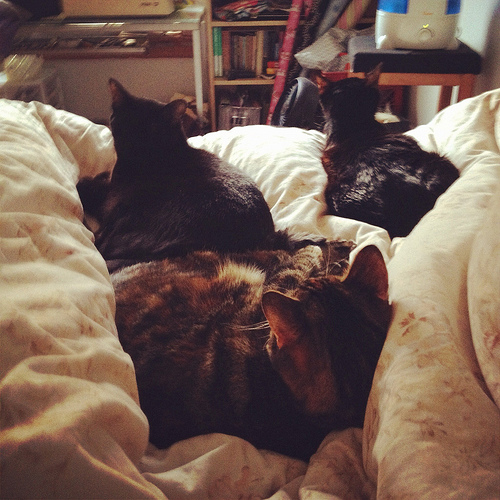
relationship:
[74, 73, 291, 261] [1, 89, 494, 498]
cat are on bed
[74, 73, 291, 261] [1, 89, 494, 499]
cat are on room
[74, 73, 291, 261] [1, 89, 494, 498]
cat are in bed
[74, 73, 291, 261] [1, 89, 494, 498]
cat are lying on a bed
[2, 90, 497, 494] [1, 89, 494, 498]
blanket on bed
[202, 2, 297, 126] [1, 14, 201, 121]
bookcase against wall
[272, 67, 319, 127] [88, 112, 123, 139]
fan on floor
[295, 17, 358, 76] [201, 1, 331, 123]
paper rolls against bookcase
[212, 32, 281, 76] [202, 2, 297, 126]
books on bookcase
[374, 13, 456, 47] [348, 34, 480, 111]
humidifier on table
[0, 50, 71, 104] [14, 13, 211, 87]
storage under desk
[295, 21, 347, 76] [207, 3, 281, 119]
paper rolls on bookcase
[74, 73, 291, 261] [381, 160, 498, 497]
cat on comforter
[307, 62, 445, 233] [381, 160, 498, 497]
cat on comforter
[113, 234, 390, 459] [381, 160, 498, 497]
cat on comforter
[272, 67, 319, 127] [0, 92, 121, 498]
fan beside bed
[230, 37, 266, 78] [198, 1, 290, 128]
books on bookshelf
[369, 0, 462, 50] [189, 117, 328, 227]
humidifier beside bed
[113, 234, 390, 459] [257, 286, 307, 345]
cat has ear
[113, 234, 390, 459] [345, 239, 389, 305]
cat has ear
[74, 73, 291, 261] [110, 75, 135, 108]
cat has ear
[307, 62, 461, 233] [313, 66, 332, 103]
cat has ear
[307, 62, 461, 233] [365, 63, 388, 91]
cat has ear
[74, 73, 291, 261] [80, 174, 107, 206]
cat has paw